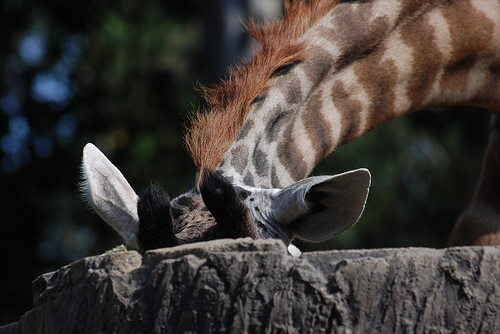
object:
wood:
[8, 240, 498, 334]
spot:
[333, 78, 367, 141]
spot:
[299, 40, 336, 90]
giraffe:
[76, 0, 499, 252]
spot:
[403, 13, 439, 118]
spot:
[272, 67, 320, 107]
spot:
[327, 7, 383, 57]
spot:
[274, 127, 309, 176]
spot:
[442, 8, 483, 68]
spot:
[254, 145, 265, 175]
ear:
[79, 142, 165, 244]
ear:
[272, 166, 370, 242]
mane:
[183, 10, 284, 165]